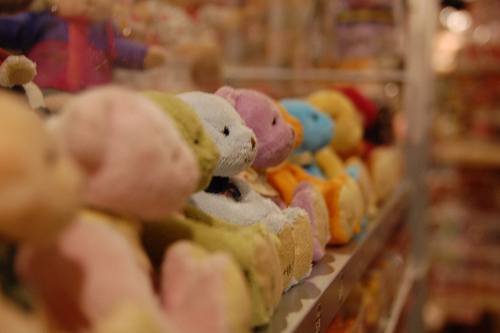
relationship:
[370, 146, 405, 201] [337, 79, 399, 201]
feet on teddy bear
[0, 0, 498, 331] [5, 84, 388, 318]
shelves holding stuffed animals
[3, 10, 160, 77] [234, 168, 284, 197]
animal wearing jacket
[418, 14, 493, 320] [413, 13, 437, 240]
area with entrance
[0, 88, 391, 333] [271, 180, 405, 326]
animal on shelf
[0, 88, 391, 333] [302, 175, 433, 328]
animal sitting on shelf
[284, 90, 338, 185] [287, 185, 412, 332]
teddy bear sitting on shelf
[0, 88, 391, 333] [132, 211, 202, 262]
animal wearing jacket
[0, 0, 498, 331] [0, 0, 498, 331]
shelves in toy store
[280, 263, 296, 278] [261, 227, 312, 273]
letter written on foot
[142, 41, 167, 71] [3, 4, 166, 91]
paw of teddy bear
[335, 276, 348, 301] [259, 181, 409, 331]
shelf sticker on a shelf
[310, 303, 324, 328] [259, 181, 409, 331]
shelf sticker on a shelf